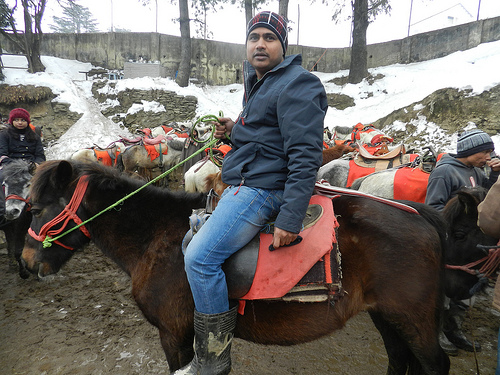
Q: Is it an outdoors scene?
A: Yes, it is outdoors.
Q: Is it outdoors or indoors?
A: It is outdoors.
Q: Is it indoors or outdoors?
A: It is outdoors.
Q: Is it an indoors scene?
A: No, it is outdoors.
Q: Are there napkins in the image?
A: No, there are no napkins.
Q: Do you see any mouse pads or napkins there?
A: No, there are no napkins or mouse pads.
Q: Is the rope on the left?
A: Yes, the rope is on the left of the image.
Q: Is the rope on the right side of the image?
A: No, the rope is on the left of the image.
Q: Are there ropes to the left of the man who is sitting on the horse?
A: Yes, there is a rope to the left of the man.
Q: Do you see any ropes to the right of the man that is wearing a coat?
A: No, the rope is to the left of the man.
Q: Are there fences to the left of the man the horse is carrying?
A: No, there is a rope to the left of the man.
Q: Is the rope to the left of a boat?
A: No, the rope is to the left of a man.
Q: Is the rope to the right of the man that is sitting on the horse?
A: No, the rope is to the left of the man.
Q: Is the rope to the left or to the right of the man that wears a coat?
A: The rope is to the left of the man.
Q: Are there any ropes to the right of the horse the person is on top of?
A: Yes, there is a rope to the right of the horse.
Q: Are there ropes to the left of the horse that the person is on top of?
A: No, the rope is to the right of the horse.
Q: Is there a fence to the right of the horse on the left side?
A: No, there is a rope to the right of the horse.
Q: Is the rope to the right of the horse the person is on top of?
A: Yes, the rope is to the right of the horse.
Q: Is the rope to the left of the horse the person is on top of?
A: No, the rope is to the right of the horse.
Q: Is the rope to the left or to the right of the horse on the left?
A: The rope is to the right of the horse.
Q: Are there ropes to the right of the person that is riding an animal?
A: Yes, there is a rope to the right of the person.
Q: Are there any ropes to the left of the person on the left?
A: No, the rope is to the right of the person.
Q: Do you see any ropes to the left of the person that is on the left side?
A: No, the rope is to the right of the person.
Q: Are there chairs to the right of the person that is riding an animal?
A: No, there is a rope to the right of the person.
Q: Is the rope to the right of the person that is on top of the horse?
A: Yes, the rope is to the right of the person.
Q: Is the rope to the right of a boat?
A: No, the rope is to the right of the person.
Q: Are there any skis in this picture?
A: No, there are no skis.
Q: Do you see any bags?
A: No, there are no bags.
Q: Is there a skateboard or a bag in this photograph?
A: No, there are no bags or skateboards.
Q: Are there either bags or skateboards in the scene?
A: No, there are no bags or skateboards.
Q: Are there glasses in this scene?
A: No, there are no glasses.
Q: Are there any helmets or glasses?
A: No, there are no glasses or helmets.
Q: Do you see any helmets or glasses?
A: No, there are no glasses or helmets.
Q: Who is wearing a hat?
A: The man is wearing a hat.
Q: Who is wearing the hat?
A: The man is wearing a hat.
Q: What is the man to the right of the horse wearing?
A: The man is wearing a hat.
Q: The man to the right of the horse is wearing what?
A: The man is wearing a hat.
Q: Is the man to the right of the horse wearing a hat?
A: Yes, the man is wearing a hat.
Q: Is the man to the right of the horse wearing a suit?
A: No, the man is wearing a hat.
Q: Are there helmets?
A: No, there are no helmets.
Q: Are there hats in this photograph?
A: Yes, there is a hat.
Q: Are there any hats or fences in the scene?
A: Yes, there is a hat.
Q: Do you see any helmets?
A: No, there are no helmets.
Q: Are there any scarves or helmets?
A: No, there are no helmets or scarves.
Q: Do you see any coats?
A: Yes, there is a coat.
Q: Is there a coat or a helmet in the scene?
A: Yes, there is a coat.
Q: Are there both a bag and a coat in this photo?
A: No, there is a coat but no bags.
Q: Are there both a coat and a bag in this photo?
A: No, there is a coat but no bags.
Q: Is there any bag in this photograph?
A: No, there are no bags.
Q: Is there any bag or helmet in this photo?
A: No, there are no bags or helmets.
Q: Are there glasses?
A: No, there are no glasses.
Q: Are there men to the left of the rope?
A: No, the man is to the right of the rope.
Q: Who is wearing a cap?
A: The man is wearing a cap.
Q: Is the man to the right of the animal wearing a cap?
A: Yes, the man is wearing a cap.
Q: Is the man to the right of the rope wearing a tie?
A: No, the man is wearing a cap.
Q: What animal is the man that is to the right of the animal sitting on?
A: The man is sitting on the horse.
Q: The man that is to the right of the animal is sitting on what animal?
A: The man is sitting on the horse.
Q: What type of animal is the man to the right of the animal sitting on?
A: The man is sitting on the horse.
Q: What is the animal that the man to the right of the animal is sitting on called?
A: The animal is a horse.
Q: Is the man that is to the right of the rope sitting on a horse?
A: Yes, the man is sitting on a horse.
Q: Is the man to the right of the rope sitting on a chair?
A: No, the man is sitting on a horse.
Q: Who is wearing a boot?
A: The man is wearing a boot.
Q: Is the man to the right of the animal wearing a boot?
A: Yes, the man is wearing a boot.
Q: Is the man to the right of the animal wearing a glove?
A: No, the man is wearing a boot.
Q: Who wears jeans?
A: The man wears jeans.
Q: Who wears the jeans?
A: The man wears jeans.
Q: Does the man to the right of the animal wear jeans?
A: Yes, the man wears jeans.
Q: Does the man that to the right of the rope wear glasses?
A: No, the man wears jeans.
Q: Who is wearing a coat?
A: The man is wearing a coat.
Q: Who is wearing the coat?
A: The man is wearing a coat.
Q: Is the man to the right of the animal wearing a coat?
A: Yes, the man is wearing a coat.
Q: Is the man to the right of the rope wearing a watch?
A: No, the man is wearing a coat.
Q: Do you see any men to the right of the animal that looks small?
A: Yes, there is a man to the right of the animal.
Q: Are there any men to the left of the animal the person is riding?
A: No, the man is to the right of the animal.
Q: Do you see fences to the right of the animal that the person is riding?
A: No, there is a man to the right of the animal.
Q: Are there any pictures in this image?
A: No, there are no pictures.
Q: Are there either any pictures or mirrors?
A: No, there are no pictures or mirrors.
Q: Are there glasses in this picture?
A: No, there are no glasses.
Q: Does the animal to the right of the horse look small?
A: Yes, the animal is small.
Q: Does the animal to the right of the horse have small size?
A: Yes, the animal is small.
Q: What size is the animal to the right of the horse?
A: The animal is small.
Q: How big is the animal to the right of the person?
A: The animal is small.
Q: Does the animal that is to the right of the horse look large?
A: No, the animal is small.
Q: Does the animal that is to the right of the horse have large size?
A: No, the animal is small.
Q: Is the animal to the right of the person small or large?
A: The animal is small.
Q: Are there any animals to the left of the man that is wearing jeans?
A: Yes, there is an animal to the left of the man.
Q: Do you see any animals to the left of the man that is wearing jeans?
A: Yes, there is an animal to the left of the man.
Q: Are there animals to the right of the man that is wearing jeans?
A: No, the animal is to the left of the man.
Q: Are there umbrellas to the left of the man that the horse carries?
A: No, there is an animal to the left of the man.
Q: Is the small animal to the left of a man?
A: Yes, the animal is to the left of a man.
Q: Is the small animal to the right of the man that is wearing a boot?
A: No, the animal is to the left of the man.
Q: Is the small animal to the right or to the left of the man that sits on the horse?
A: The animal is to the left of the man.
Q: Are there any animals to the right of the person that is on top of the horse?
A: Yes, there is an animal to the right of the person.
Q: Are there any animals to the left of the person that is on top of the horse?
A: No, the animal is to the right of the person.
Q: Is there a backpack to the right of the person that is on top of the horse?
A: No, there is an animal to the right of the person.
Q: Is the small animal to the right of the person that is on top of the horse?
A: Yes, the animal is to the right of the person.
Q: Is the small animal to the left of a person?
A: No, the animal is to the right of a person.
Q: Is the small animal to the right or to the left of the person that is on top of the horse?
A: The animal is to the right of the person.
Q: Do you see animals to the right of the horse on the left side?
A: Yes, there is an animal to the right of the horse.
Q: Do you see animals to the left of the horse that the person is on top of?
A: No, the animal is to the right of the horse.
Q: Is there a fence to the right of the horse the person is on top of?
A: No, there is an animal to the right of the horse.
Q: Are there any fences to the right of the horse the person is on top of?
A: No, there is an animal to the right of the horse.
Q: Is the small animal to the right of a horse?
A: Yes, the animal is to the right of a horse.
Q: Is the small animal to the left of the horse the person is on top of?
A: No, the animal is to the right of the horse.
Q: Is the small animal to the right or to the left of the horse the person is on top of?
A: The animal is to the right of the horse.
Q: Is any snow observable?
A: Yes, there is snow.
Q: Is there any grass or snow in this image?
A: Yes, there is snow.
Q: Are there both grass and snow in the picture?
A: No, there is snow but no grass.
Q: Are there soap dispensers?
A: No, there are no soap dispensers.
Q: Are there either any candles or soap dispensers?
A: No, there are no soap dispensers or candles.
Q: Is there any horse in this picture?
A: Yes, there is a horse.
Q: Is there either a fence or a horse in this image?
A: Yes, there is a horse.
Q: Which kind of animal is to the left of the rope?
A: The animal is a horse.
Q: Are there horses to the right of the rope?
A: No, the horse is to the left of the rope.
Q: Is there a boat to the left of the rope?
A: No, there is a horse to the left of the rope.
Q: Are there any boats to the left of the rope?
A: No, there is a horse to the left of the rope.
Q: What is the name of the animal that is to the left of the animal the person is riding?
A: The animal is a horse.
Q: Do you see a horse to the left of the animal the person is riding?
A: Yes, there is a horse to the left of the animal.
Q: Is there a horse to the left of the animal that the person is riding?
A: Yes, there is a horse to the left of the animal.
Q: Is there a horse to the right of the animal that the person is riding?
A: No, the horse is to the left of the animal.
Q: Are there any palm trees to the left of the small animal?
A: No, there is a horse to the left of the animal.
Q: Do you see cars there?
A: No, there are no cars.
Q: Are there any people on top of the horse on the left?
A: Yes, there is a person on top of the horse.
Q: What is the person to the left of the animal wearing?
A: The person is wearing a cap.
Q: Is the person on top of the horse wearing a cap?
A: Yes, the person is wearing a cap.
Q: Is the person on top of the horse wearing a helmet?
A: No, the person is wearing a cap.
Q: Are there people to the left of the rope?
A: Yes, there is a person to the left of the rope.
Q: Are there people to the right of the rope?
A: No, the person is to the left of the rope.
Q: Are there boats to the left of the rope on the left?
A: No, there is a person to the left of the rope.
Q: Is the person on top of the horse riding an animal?
A: Yes, the person is riding an animal.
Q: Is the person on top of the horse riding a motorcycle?
A: No, the person is riding an animal.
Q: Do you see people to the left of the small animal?
A: Yes, there is a person to the left of the animal.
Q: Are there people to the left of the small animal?
A: Yes, there is a person to the left of the animal.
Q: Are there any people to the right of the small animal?
A: No, the person is to the left of the animal.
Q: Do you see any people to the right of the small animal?
A: No, the person is to the left of the animal.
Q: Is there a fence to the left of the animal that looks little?
A: No, there is a person to the left of the animal.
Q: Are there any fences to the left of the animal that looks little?
A: No, there is a person to the left of the animal.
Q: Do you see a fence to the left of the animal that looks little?
A: No, there is a person to the left of the animal.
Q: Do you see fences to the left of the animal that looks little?
A: No, there is a person to the left of the animal.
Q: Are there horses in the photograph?
A: Yes, there is a horse.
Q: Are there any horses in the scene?
A: Yes, there is a horse.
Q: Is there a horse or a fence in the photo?
A: Yes, there is a horse.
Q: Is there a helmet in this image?
A: No, there are no helmets.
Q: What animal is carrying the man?
A: The horse is carrying the man.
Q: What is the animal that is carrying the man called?
A: The animal is a horse.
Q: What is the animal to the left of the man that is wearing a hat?
A: The animal is a horse.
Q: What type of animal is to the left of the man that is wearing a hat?
A: The animal is a horse.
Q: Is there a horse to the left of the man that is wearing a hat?
A: Yes, there is a horse to the left of the man.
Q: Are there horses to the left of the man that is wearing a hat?
A: Yes, there is a horse to the left of the man.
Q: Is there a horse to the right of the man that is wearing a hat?
A: No, the horse is to the left of the man.